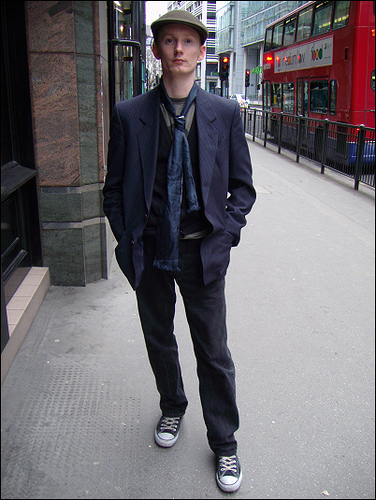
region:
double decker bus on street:
[255, 7, 371, 173]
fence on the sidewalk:
[249, 103, 375, 179]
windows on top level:
[272, 16, 340, 38]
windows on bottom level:
[274, 85, 340, 114]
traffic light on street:
[212, 49, 229, 79]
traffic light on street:
[241, 64, 253, 90]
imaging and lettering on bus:
[268, 43, 333, 70]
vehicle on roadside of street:
[230, 87, 248, 108]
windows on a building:
[212, 13, 230, 48]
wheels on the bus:
[266, 115, 325, 149]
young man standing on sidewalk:
[94, 7, 265, 492]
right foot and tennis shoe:
[147, 397, 190, 454]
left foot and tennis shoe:
[198, 441, 249, 495]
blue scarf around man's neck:
[149, 80, 208, 284]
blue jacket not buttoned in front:
[95, 76, 263, 287]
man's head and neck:
[136, 4, 217, 98]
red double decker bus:
[251, 0, 371, 174]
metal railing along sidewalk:
[239, 101, 374, 190]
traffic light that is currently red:
[212, 48, 235, 89]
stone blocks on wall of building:
[23, 5, 106, 284]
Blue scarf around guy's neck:
[148, 71, 207, 275]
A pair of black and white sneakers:
[148, 409, 245, 494]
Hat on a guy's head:
[145, 7, 210, 77]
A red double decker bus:
[256, 2, 374, 171]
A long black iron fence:
[235, 99, 373, 197]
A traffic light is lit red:
[212, 52, 234, 84]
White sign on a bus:
[270, 31, 336, 76]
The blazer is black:
[97, 80, 262, 291]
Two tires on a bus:
[268, 113, 331, 166]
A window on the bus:
[303, 77, 339, 118]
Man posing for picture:
[97, 9, 258, 494]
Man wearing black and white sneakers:
[152, 413, 243, 494]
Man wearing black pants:
[135, 238, 240, 453]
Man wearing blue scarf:
[150, 81, 201, 278]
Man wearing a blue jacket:
[100, 82, 257, 286]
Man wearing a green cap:
[150, 8, 209, 42]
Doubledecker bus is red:
[258, 1, 375, 172]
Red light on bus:
[265, 52, 273, 71]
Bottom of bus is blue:
[260, 118, 375, 169]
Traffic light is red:
[217, 52, 229, 82]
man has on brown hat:
[150, 10, 207, 75]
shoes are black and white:
[150, 410, 244, 493]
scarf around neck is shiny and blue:
[155, 82, 201, 270]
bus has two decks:
[260, 7, 374, 165]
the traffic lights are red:
[218, 50, 251, 88]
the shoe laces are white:
[219, 453, 237, 474]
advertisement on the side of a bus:
[269, 44, 341, 71]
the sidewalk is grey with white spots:
[256, 397, 365, 485]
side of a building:
[37, 33, 111, 288]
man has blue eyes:
[162, 36, 193, 46]